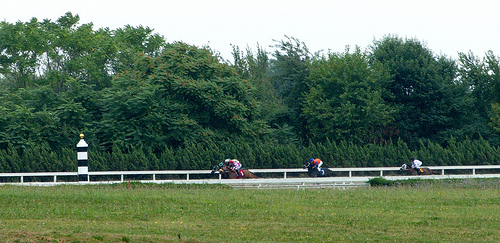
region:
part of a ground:
[364, 189, 423, 231]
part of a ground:
[361, 183, 391, 211]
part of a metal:
[159, 163, 174, 180]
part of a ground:
[389, 193, 423, 230]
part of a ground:
[358, 192, 397, 224]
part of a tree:
[136, 45, 179, 110]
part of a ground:
[366, 132, 406, 219]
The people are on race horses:
[11, 90, 491, 226]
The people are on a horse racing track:
[11, 75, 487, 226]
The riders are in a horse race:
[8, 87, 489, 223]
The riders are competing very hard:
[15, 80, 496, 222]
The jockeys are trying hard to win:
[10, 87, 493, 223]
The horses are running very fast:
[10, 111, 495, 238]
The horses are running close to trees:
[0, 96, 485, 232]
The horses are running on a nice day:
[12, 68, 497, 229]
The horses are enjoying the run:
[1, 62, 481, 234]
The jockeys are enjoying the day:
[20, 60, 495, 232]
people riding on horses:
[207, 147, 447, 185]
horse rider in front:
[205, 146, 262, 183]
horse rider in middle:
[302, 144, 346, 184]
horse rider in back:
[392, 149, 439, 179]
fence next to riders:
[0, 165, 493, 180]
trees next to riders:
[4, 13, 495, 163]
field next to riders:
[6, 188, 491, 238]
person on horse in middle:
[310, 152, 322, 167]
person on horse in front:
[225, 155, 240, 165]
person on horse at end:
[405, 157, 425, 167]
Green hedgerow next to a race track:
[1, 138, 499, 167]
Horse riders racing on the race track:
[203, 156, 441, 181]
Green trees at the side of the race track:
[1, 37, 498, 139]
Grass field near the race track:
[0, 186, 498, 239]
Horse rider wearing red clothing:
[309, 155, 326, 172]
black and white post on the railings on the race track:
[73, 131, 90, 182]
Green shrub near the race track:
[365, 175, 499, 187]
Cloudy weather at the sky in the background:
[1, 1, 498, 51]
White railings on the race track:
[2, 173, 498, 189]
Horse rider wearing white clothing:
[409, 156, 424, 171]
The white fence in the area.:
[2, 163, 499, 188]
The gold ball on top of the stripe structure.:
[79, 133, 84, 138]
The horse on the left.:
[213, 152, 259, 177]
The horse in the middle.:
[300, 160, 337, 172]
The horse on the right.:
[398, 161, 433, 171]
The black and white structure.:
[74, 150, 91, 179]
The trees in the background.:
[10, 22, 494, 161]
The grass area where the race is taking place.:
[4, 185, 489, 241]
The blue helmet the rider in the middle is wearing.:
[310, 155, 314, 162]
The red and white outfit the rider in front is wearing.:
[232, 161, 242, 172]